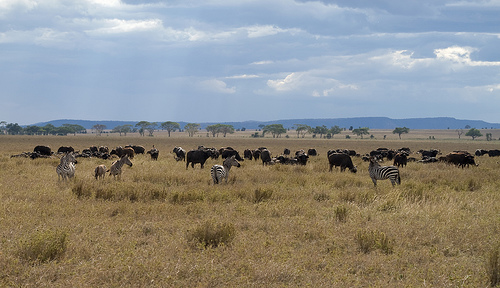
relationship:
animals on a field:
[171, 128, 422, 191] [0, 130, 499, 287]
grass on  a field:
[153, 232, 370, 254] [0, 130, 499, 287]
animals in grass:
[210, 157, 239, 184] [153, 232, 370, 254]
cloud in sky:
[383, 46, 483, 78] [395, 1, 495, 41]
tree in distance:
[153, 116, 184, 140] [154, 103, 194, 113]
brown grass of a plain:
[132, 135, 210, 144] [106, 129, 282, 139]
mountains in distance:
[98, 116, 131, 127] [154, 103, 194, 113]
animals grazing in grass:
[171, 128, 422, 191] [153, 232, 370, 254]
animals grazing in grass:
[210, 157, 239, 184] [153, 232, 370, 254]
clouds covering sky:
[89, 11, 324, 94] [395, 1, 495, 41]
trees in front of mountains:
[132, 119, 381, 143] [98, 116, 131, 127]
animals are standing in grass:
[171, 128, 422, 191] [153, 232, 370, 254]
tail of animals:
[214, 176, 221, 181] [210, 157, 239, 184]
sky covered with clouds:
[395, 1, 495, 41] [89, 11, 324, 94]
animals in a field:
[171, 128, 422, 191] [187, 180, 429, 242]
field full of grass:
[187, 180, 429, 242] [153, 232, 370, 254]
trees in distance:
[132, 119, 381, 143] [154, 103, 194, 113]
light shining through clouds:
[151, 49, 362, 112] [89, 11, 324, 94]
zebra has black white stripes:
[361, 145, 406, 196] [378, 169, 397, 177]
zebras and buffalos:
[50, 145, 142, 186] [86, 141, 151, 160]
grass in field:
[153, 232, 370, 254] [187, 180, 429, 242]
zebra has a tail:
[361, 145, 406, 196] [396, 175, 404, 186]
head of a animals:
[222, 151, 242, 171] [210, 157, 239, 184]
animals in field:
[171, 128, 422, 191] [187, 180, 429, 242]